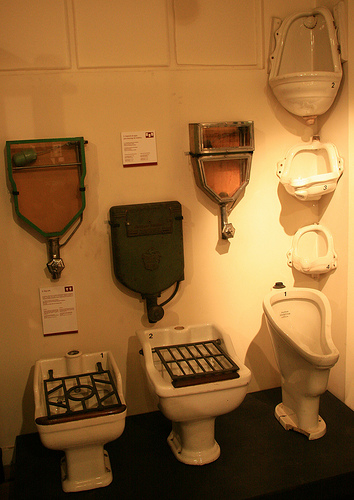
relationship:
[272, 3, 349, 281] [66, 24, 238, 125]
fixtures on wall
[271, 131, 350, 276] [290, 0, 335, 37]
urinals in corner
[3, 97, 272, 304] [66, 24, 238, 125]
tanks on wall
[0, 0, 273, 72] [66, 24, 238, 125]
panels on wall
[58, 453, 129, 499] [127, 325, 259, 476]
base of toilet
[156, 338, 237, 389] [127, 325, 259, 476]
seat of toilet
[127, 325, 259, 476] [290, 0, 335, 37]
toilet in corner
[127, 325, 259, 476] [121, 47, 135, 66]
toilet for men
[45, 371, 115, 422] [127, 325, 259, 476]
grid on toilet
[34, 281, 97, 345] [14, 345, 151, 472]
sign over toilet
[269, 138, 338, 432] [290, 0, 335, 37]
toilets in corner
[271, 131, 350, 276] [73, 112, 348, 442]
urinals on display